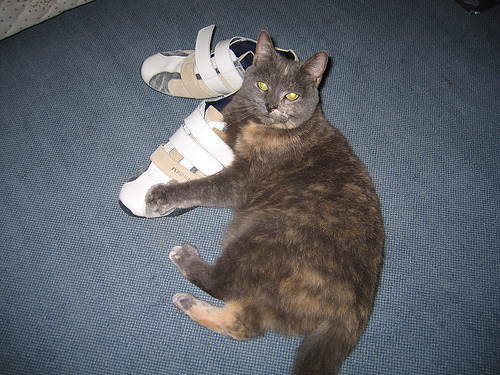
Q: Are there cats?
A: Yes, there is a cat.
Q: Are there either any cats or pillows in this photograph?
A: Yes, there is a cat.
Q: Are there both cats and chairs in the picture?
A: No, there is a cat but no chairs.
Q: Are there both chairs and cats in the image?
A: No, there is a cat but no chairs.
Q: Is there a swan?
A: No, there are no swans.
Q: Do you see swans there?
A: No, there are no swans.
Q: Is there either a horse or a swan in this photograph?
A: No, there are no swans or horses.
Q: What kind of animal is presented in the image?
A: The animal is a cat.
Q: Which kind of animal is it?
A: The animal is a cat.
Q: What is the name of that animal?
A: This is a cat.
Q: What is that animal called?
A: This is a cat.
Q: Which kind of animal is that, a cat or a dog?
A: This is a cat.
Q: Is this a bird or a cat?
A: This is a cat.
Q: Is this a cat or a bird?
A: This is a cat.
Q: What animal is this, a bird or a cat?
A: This is a cat.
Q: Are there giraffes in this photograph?
A: No, there are no giraffes.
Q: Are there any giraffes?
A: No, there are no giraffes.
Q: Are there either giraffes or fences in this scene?
A: No, there are no giraffes or fences.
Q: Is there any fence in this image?
A: No, there are no fences.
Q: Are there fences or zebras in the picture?
A: No, there are no fences or zebras.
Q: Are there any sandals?
A: Yes, there are sandals.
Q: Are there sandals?
A: Yes, there are sandals.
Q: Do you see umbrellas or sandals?
A: Yes, there are sandals.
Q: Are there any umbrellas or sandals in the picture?
A: Yes, there are sandals.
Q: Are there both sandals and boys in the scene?
A: No, there are sandals but no boys.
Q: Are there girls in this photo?
A: No, there are no girls.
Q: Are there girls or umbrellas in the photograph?
A: No, there are no girls or umbrellas.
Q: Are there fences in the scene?
A: No, there are no fences.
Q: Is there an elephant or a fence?
A: No, there are no fences or elephants.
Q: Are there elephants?
A: No, there are no elephants.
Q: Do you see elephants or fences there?
A: No, there are no elephants or fences.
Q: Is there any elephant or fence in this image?
A: No, there are no elephants or fences.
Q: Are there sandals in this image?
A: Yes, there are sandals.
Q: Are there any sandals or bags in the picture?
A: Yes, there are sandals.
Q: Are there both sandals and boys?
A: No, there are sandals but no boys.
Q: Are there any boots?
A: No, there are no boots.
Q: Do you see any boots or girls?
A: No, there are no boots or girls.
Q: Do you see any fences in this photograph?
A: No, there are no fences.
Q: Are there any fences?
A: No, there are no fences.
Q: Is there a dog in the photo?
A: No, there are no dogs.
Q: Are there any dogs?
A: No, there are no dogs.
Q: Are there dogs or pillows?
A: No, there are no dogs or pillows.